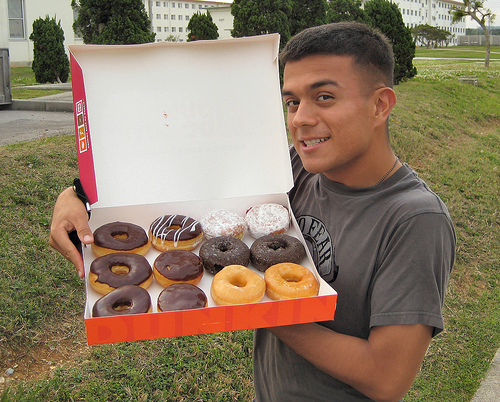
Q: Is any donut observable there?
A: Yes, there is a donut.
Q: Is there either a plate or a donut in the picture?
A: Yes, there is a donut.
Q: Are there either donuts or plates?
A: Yes, there is a donut.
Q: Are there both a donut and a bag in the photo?
A: No, there is a donut but no bags.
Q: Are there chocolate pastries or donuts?
A: Yes, there is a chocolate donut.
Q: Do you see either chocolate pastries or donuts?
A: Yes, there is a chocolate donut.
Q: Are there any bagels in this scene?
A: No, there are no bagels.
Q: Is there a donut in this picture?
A: Yes, there is a donut.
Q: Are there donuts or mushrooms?
A: Yes, there is a donut.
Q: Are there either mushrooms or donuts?
A: Yes, there is a donut.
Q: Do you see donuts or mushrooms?
A: Yes, there is a donut.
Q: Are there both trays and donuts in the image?
A: No, there is a donut but no trays.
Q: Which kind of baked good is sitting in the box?
A: The food is a donut.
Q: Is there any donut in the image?
A: Yes, there is a donut.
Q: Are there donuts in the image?
A: Yes, there is a donut.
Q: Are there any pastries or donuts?
A: Yes, there is a donut.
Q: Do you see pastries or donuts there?
A: Yes, there is a donut.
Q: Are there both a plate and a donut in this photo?
A: No, there is a donut but no plates.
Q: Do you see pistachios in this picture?
A: No, there are no pistachios.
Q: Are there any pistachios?
A: No, there are no pistachios.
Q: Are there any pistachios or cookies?
A: No, there are no pistachios or cookies.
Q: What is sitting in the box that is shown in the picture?
A: The donut is sitting in the box.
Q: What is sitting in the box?
A: The donut is sitting in the box.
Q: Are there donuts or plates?
A: Yes, there is a donut.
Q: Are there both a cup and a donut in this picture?
A: No, there is a donut but no cups.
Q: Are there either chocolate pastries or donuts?
A: Yes, there is a chocolate donut.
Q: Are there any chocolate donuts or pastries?
A: Yes, there is a chocolate donut.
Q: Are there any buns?
A: No, there are no buns.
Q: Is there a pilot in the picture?
A: No, there are no pilots.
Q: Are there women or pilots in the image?
A: No, there are no pilots or women.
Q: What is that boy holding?
A: The boy is holding the donut.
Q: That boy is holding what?
A: The boy is holding the donut.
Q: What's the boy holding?
A: The boy is holding the donut.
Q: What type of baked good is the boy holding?
A: The boy is holding the donut.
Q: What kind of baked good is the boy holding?
A: The boy is holding the donut.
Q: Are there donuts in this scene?
A: Yes, there is a donut.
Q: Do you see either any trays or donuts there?
A: Yes, there is a donut.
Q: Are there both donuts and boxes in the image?
A: Yes, there are both a donut and a box.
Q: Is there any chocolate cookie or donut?
A: Yes, there is a chocolate donut.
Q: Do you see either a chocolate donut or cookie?
A: Yes, there is a chocolate donut.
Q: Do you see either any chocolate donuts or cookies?
A: Yes, there is a chocolate donut.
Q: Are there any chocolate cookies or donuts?
A: Yes, there is a chocolate donut.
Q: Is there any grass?
A: Yes, there is grass.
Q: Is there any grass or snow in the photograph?
A: Yes, there is grass.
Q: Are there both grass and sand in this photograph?
A: No, there is grass but no sand.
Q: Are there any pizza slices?
A: No, there are no pizza slices.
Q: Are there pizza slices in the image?
A: No, there are no pizza slices.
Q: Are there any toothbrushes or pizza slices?
A: No, there are no pizza slices or toothbrushes.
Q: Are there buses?
A: No, there are no buses.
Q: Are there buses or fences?
A: No, there are no buses or fences.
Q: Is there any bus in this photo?
A: No, there are no buses.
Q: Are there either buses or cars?
A: No, there are no buses or cars.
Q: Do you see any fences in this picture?
A: No, there are no fences.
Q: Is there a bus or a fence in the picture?
A: No, there are no fences or buses.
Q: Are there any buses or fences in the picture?
A: No, there are no fences or buses.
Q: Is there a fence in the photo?
A: No, there are no fences.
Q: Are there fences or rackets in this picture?
A: No, there are no fences or rackets.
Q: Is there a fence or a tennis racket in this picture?
A: No, there are no fences or rackets.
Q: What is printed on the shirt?
A: The logo is printed on the shirt.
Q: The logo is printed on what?
A: The logo is printed on the shirt.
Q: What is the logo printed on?
A: The logo is printed on the shirt.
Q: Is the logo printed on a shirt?
A: Yes, the logo is printed on a shirt.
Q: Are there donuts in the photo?
A: Yes, there is a donut.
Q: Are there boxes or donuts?
A: Yes, there is a donut.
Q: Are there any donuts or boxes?
A: Yes, there is a donut.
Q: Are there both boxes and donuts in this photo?
A: Yes, there are both a donut and a box.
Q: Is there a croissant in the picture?
A: No, there are no croissants.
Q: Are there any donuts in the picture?
A: Yes, there is a donut.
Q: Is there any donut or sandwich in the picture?
A: Yes, there is a donut.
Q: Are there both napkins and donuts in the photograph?
A: No, there is a donut but no napkins.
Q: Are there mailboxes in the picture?
A: No, there are no mailboxes.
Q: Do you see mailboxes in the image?
A: No, there are no mailboxes.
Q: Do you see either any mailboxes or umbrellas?
A: No, there are no mailboxes or umbrellas.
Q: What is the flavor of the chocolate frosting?
A: That is a chocolate frosting.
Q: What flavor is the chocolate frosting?
A: That is a chocolate frosting.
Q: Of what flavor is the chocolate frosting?
A: That is a chocolate frosting.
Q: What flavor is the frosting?
A: That is a chocolate frosting.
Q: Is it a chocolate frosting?
A: Yes, that is a chocolate frosting.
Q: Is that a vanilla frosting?
A: No, that is a chocolate frosting.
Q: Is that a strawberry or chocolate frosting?
A: That is a chocolate frosting.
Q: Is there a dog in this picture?
A: No, there are no dogs.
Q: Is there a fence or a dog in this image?
A: No, there are no dogs or fences.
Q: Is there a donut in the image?
A: Yes, there is a donut.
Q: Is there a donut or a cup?
A: Yes, there is a donut.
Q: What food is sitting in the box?
A: The food is a donut.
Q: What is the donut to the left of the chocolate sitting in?
A: The doughnut is sitting in the box.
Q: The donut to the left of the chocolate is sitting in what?
A: The doughnut is sitting in the box.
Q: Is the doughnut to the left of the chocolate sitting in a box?
A: Yes, the donut is sitting in a box.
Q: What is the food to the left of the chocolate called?
A: The food is a donut.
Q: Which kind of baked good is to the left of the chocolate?
A: The food is a donut.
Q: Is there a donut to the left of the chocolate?
A: Yes, there is a donut to the left of the chocolate.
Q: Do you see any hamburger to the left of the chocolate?
A: No, there is a donut to the left of the chocolate.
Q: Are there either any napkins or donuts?
A: Yes, there is a donut.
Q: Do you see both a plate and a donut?
A: No, there is a donut but no plates.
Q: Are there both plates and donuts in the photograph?
A: No, there is a donut but no plates.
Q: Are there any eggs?
A: No, there are no eggs.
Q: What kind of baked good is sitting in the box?
A: The food is a donut.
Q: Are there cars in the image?
A: No, there are no cars.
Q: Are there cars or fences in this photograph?
A: No, there are no cars or fences.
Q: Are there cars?
A: No, there are no cars.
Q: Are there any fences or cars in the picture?
A: No, there are no cars or fences.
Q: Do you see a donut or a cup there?
A: Yes, there is a donut.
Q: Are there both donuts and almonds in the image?
A: No, there is a donut but no almonds.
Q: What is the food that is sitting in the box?
A: The food is a donut.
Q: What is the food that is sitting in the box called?
A: The food is a donut.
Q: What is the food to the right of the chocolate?
A: The food is a donut.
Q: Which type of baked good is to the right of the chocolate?
A: The food is a donut.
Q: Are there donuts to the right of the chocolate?
A: Yes, there is a donut to the right of the chocolate.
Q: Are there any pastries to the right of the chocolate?
A: No, there is a donut to the right of the chocolate.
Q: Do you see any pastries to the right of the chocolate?
A: No, there is a donut to the right of the chocolate.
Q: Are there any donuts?
A: Yes, there is a donut.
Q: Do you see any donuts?
A: Yes, there is a donut.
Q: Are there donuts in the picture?
A: Yes, there is a donut.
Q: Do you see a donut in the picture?
A: Yes, there is a donut.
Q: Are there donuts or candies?
A: Yes, there is a donut.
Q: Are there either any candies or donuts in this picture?
A: Yes, there is a donut.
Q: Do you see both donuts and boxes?
A: Yes, there are both a donut and a box.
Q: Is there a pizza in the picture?
A: No, there are no pizzas.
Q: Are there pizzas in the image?
A: No, there are no pizzas.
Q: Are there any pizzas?
A: No, there are no pizzas.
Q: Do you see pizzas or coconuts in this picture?
A: No, there are no pizzas or coconuts.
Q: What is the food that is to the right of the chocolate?
A: The food is a donut.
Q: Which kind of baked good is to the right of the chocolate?
A: The food is a donut.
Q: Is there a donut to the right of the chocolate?
A: Yes, there is a donut to the right of the chocolate.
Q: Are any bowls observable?
A: No, there are no bowls.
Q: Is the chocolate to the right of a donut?
A: Yes, the chocolate is to the right of a donut.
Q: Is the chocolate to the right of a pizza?
A: No, the chocolate is to the right of a donut.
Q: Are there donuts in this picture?
A: Yes, there is a donut.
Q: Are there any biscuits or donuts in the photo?
A: Yes, there is a donut.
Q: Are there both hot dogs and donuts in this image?
A: No, there is a donut but no hot dogs.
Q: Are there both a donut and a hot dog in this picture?
A: No, there is a donut but no hot dogs.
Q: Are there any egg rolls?
A: No, there are no egg rolls.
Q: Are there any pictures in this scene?
A: No, there are no pictures.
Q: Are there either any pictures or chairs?
A: No, there are no pictures or chairs.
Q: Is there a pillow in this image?
A: No, there are no pillows.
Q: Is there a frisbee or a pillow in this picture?
A: No, there are no pillows or frisbees.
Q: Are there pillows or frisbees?
A: No, there are no pillows or frisbees.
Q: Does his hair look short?
A: Yes, the hair is short.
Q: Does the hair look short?
A: Yes, the hair is short.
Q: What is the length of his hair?
A: The hair is short.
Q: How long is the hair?
A: The hair is short.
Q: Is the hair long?
A: No, the hair is short.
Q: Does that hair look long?
A: No, the hair is short.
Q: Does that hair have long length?
A: No, the hair is short.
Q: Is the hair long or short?
A: The hair is short.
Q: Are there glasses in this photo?
A: No, there are no glasses.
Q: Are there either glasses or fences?
A: No, there are no glasses or fences.